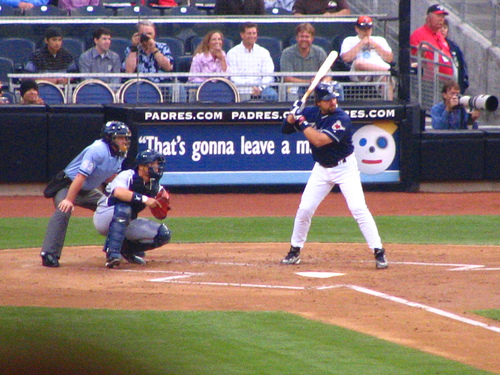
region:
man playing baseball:
[239, 22, 439, 364]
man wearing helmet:
[264, 72, 434, 364]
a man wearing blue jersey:
[243, 26, 448, 357]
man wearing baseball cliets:
[261, 67, 465, 372]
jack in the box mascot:
[348, 108, 396, 178]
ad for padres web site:
[144, 108, 224, 123]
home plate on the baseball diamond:
[293, 265, 343, 278]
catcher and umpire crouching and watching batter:
[36, 116, 173, 268]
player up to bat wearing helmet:
[281, 49, 388, 272]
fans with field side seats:
[29, 14, 379, 86]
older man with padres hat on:
[412, 3, 454, 105]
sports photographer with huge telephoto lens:
[426, 80, 498, 131]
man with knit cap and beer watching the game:
[15, 75, 45, 104]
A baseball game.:
[6, 7, 496, 362]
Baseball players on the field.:
[27, 48, 403, 271]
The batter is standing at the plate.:
[270, 48, 399, 273]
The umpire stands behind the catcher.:
[30, 112, 180, 277]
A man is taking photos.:
[122, 14, 177, 98]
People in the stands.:
[5, 0, 497, 137]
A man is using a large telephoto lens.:
[430, 78, 497, 139]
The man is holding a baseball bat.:
[279, 43, 398, 270]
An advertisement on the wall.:
[125, 102, 412, 192]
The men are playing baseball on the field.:
[26, 45, 407, 277]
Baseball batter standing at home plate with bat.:
[270, 42, 404, 295]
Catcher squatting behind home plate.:
[84, 148, 479, 329]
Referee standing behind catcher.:
[15, 79, 200, 304]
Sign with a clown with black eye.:
[120, 104, 430, 196]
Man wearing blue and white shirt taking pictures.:
[120, 16, 175, 91]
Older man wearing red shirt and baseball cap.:
[411, 3, 462, 94]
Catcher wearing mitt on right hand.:
[105, 145, 186, 257]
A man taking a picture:
[122, 23, 173, 73]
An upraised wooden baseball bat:
[285, 40, 345, 118]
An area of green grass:
[121, 320, 324, 367]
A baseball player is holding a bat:
[275, 41, 401, 274]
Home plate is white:
[285, 260, 347, 285]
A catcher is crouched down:
[85, 140, 177, 272]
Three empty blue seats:
[66, 65, 246, 110]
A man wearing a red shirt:
[405, 0, 465, 80]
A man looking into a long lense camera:
[421, 76, 496, 131]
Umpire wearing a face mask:
[91, 110, 136, 161]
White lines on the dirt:
[102, 250, 494, 340]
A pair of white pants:
[280, 140, 387, 255]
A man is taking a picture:
[118, 15, 179, 87]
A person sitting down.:
[235, 17, 287, 123]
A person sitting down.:
[198, 25, 245, 97]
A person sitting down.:
[123, 11, 179, 95]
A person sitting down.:
[92, 26, 133, 91]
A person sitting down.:
[26, 27, 78, 70]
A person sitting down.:
[18, 79, 45, 118]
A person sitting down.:
[215, 17, 288, 109]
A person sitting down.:
[278, 17, 329, 93]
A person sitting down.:
[332, 21, 390, 110]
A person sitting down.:
[440, 82, 484, 142]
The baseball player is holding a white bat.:
[289, 49, 340, 122]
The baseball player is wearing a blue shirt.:
[300, 115, 359, 165]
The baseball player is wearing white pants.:
[272, 156, 392, 247]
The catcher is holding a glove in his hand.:
[142, 189, 184, 226]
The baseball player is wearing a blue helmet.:
[316, 76, 346, 104]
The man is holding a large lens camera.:
[450, 88, 495, 114]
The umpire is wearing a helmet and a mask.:
[100, 113, 140, 157]